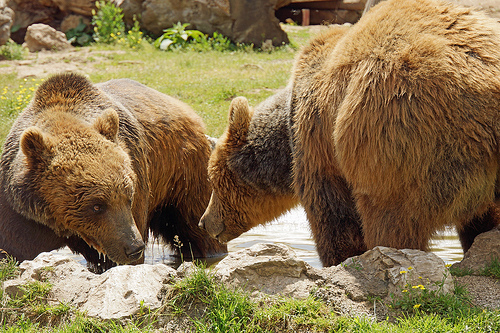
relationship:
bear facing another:
[0, 71, 225, 277] [90, 124, 258, 247]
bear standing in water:
[0, 71, 225, 277] [95, 210, 499, 273]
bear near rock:
[6, 56, 170, 249] [43, 257, 170, 302]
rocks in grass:
[58, 251, 400, 286] [190, 281, 279, 332]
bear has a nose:
[6, 56, 170, 249] [127, 240, 148, 258]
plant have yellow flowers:
[92, 5, 146, 48] [107, 31, 126, 42]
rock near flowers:
[26, 18, 81, 60] [92, 5, 146, 48]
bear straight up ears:
[6, 56, 170, 249] [95, 105, 125, 138]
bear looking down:
[6, 56, 170, 249] [90, 194, 113, 266]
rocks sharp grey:
[58, 251, 400, 286] [121, 285, 144, 301]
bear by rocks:
[0, 71, 225, 277] [58, 251, 400, 286]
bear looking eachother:
[0, 71, 225, 277] [90, 124, 258, 247]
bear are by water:
[0, 71, 225, 277] [95, 210, 499, 273]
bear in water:
[0, 71, 225, 277] [95, 210, 499, 273]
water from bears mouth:
[95, 250, 109, 272] [108, 236, 151, 268]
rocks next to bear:
[58, 251, 400, 286] [0, 71, 225, 277]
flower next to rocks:
[88, 0, 148, 48] [58, 251, 400, 286]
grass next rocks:
[190, 281, 279, 332] [58, 251, 400, 286]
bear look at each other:
[0, 71, 225, 277] [27, 95, 286, 261]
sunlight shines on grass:
[154, 43, 247, 77] [126, 56, 181, 76]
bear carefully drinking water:
[0, 71, 225, 277] [95, 210, 499, 273]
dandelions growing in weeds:
[102, 26, 141, 44] [90, 4, 153, 46]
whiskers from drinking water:
[87, 234, 136, 266] [95, 210, 499, 273]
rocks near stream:
[58, 251, 400, 286] [259, 230, 290, 257]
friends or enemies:
[52, 87, 255, 211] [124, 151, 228, 214]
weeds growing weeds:
[90, 4, 153, 46] [90, 4, 153, 46]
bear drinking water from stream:
[0, 71, 225, 277] [259, 230, 290, 257]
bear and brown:
[0, 71, 225, 277] [423, 71, 443, 94]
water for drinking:
[95, 210, 499, 273] [90, 248, 179, 268]